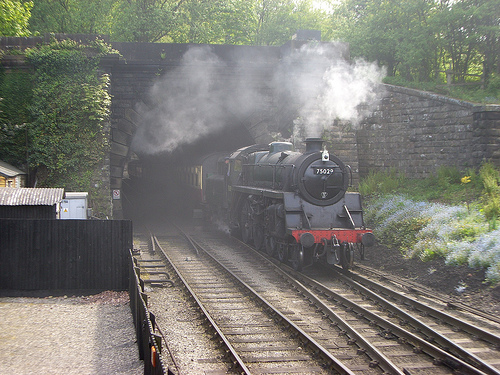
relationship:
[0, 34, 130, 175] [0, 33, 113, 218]
ivy on brick wall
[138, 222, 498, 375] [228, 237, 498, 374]
track next to track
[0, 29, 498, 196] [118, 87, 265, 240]
overpath with tunnel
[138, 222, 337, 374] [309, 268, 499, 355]
track next to track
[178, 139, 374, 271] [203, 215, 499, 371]
train on tracks